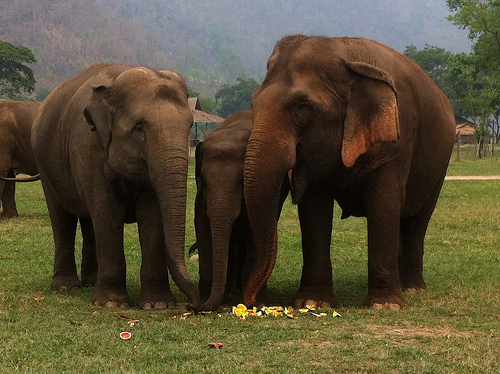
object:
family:
[16, 27, 465, 319]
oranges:
[330, 309, 343, 320]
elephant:
[29, 56, 213, 312]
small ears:
[78, 80, 122, 152]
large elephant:
[227, 21, 464, 316]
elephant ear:
[335, 58, 405, 168]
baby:
[187, 112, 299, 312]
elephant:
[0, 94, 58, 222]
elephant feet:
[290, 282, 340, 314]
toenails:
[320, 300, 333, 311]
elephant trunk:
[234, 136, 295, 311]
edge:
[334, 105, 405, 167]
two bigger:
[77, 60, 205, 199]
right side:
[273, 0, 500, 373]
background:
[3, 0, 500, 165]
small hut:
[181, 93, 229, 144]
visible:
[133, 14, 238, 69]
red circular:
[205, 339, 227, 352]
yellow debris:
[239, 308, 244, 313]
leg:
[86, 199, 137, 311]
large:
[455, 176, 500, 248]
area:
[340, 296, 476, 331]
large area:
[4, 0, 500, 222]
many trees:
[445, 34, 500, 159]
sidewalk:
[445, 171, 500, 184]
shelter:
[448, 120, 500, 163]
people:
[463, 107, 495, 155]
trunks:
[194, 161, 248, 311]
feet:
[359, 280, 412, 313]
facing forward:
[62, 69, 390, 212]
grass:
[0, 133, 500, 374]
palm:
[210, 74, 264, 118]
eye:
[127, 122, 150, 140]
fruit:
[229, 299, 252, 320]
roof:
[188, 95, 229, 125]